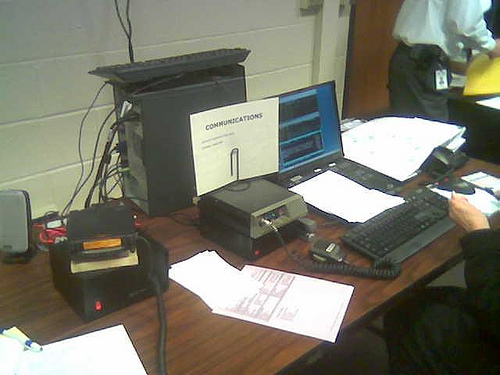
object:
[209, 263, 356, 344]
paper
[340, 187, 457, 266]
keyboard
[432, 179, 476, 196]
mouse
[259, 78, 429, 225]
computer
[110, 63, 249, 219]
cpu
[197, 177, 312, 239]
cb radio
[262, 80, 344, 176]
computer screen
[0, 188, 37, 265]
speaker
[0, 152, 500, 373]
desk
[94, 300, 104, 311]
switch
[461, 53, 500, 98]
folder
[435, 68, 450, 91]
id badge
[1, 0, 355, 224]
wall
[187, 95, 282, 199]
sign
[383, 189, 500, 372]
man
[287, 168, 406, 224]
paper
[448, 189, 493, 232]
hand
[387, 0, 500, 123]
man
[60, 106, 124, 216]
electrical line